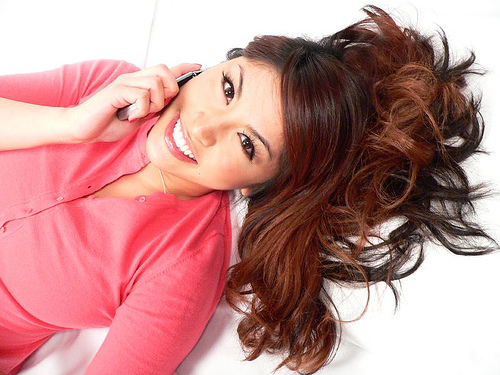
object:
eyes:
[235, 130, 260, 164]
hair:
[223, 4, 499, 375]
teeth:
[172, 119, 194, 159]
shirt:
[0, 58, 233, 375]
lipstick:
[164, 114, 199, 164]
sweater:
[70, 237, 157, 284]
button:
[139, 196, 146, 202]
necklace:
[158, 169, 167, 194]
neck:
[140, 163, 215, 205]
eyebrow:
[235, 63, 245, 100]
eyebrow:
[244, 124, 273, 160]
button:
[24, 209, 32, 215]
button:
[0, 226, 4, 233]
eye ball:
[239, 133, 253, 154]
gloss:
[147, 142, 172, 161]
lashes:
[235, 130, 263, 162]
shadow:
[330, 329, 361, 367]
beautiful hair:
[222, 2, 499, 375]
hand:
[62, 63, 203, 145]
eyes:
[220, 70, 238, 106]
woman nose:
[191, 113, 232, 148]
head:
[143, 4, 500, 375]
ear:
[241, 184, 268, 197]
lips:
[163, 109, 198, 165]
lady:
[0, 5, 500, 375]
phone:
[116, 70, 203, 121]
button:
[56, 196, 64, 201]